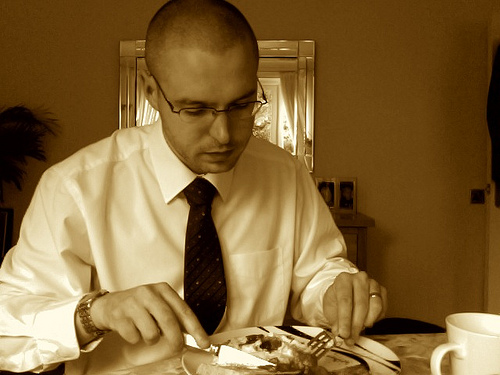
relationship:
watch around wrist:
[78, 289, 109, 340] [77, 289, 106, 337]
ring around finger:
[370, 293, 383, 299] [365, 280, 384, 329]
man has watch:
[2, 2, 389, 350] [78, 289, 109, 340]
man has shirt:
[2, 2, 389, 350] [2, 120, 367, 375]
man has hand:
[2, 2, 389, 350] [307, 260, 389, 347]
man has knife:
[2, 2, 389, 350] [182, 334, 276, 371]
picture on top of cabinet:
[339, 178, 358, 222] [332, 212, 374, 286]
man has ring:
[2, 2, 389, 350] [370, 293, 383, 299]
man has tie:
[2, 2, 389, 350] [184, 178, 228, 334]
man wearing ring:
[2, 2, 389, 350] [370, 293, 383, 299]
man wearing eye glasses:
[2, 2, 389, 350] [151, 73, 269, 123]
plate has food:
[182, 326, 401, 374] [215, 334, 336, 375]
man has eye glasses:
[2, 2, 389, 350] [151, 73, 269, 123]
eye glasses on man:
[149, 72, 269, 123] [2, 2, 389, 350]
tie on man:
[184, 178, 228, 334] [2, 2, 389, 350]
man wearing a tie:
[2, 2, 389, 350] [184, 178, 228, 334]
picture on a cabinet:
[319, 178, 358, 219] [330, 209, 377, 272]